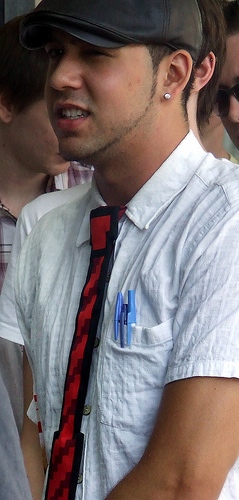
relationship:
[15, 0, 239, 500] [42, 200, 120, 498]
guy wearing tie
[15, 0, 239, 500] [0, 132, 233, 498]
guy wearing shirt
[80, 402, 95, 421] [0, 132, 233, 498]
button on shirt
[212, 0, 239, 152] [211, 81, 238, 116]
person wearing sunglasses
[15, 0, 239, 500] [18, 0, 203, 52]
guy wearing cap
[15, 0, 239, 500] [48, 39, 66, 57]
guy has eye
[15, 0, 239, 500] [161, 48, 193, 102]
guy has ear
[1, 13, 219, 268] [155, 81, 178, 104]
guy has earring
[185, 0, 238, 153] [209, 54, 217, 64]
person has cartlidge piercing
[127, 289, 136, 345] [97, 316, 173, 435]
pen in pocket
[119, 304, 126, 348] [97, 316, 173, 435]
pen in pocket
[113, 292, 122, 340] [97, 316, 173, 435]
pen in pocket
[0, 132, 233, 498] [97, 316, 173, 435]
shirt has pocket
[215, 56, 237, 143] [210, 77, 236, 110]
person wearing sunglasses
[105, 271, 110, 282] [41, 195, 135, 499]
button behind tie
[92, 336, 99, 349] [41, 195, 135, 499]
button behind tie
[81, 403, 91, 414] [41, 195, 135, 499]
button behind tie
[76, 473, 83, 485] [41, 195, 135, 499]
button behind tie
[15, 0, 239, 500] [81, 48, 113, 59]
guy has eye